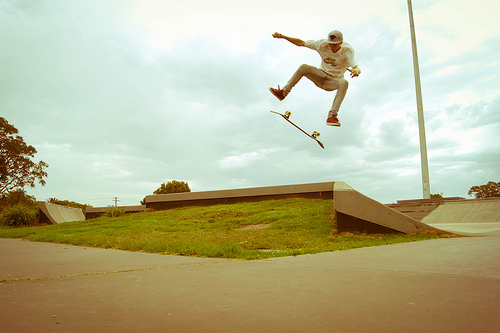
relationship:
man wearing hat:
[272, 30, 364, 131] [324, 29, 344, 48]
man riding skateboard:
[272, 30, 364, 131] [270, 106, 325, 150]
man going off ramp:
[272, 30, 364, 131] [328, 182, 469, 237]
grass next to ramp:
[11, 201, 452, 256] [328, 182, 469, 237]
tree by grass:
[3, 117, 51, 204] [11, 201, 452, 256]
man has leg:
[272, 30, 364, 131] [281, 63, 325, 97]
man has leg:
[272, 30, 364, 131] [323, 71, 351, 116]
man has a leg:
[272, 30, 364, 131] [281, 63, 325, 97]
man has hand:
[272, 30, 364, 131] [348, 66, 359, 78]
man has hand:
[272, 30, 364, 131] [273, 30, 286, 40]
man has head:
[272, 30, 364, 131] [326, 30, 344, 54]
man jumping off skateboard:
[272, 30, 364, 131] [270, 106, 325, 150]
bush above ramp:
[8, 190, 95, 208] [31, 201, 91, 224]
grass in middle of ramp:
[11, 201, 452, 256] [328, 182, 469, 237]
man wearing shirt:
[272, 30, 364, 131] [303, 41, 358, 78]